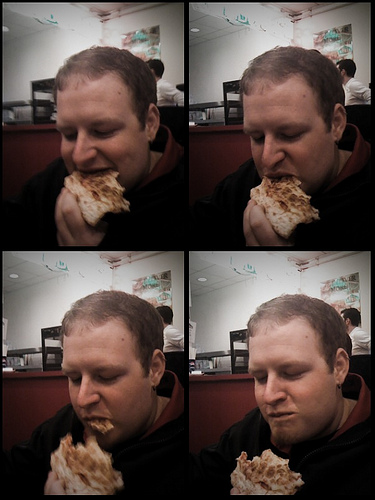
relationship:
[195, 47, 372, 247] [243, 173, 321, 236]
man eating pizza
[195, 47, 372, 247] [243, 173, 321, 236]
man biting pizza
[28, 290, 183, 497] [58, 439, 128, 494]
man chewing pizza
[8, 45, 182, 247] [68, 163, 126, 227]
man eating food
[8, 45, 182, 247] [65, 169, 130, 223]
man eating food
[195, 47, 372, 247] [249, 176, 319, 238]
man eating food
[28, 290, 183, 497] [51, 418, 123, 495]
man eating food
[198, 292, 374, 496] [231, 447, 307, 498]
man eating food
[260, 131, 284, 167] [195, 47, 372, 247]
nose of a man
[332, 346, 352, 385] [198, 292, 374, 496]
ear of a man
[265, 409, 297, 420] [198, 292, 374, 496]
lips of a man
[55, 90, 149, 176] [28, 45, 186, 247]
face of a man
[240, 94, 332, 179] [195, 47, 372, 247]
face of a man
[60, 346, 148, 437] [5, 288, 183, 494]
face of a man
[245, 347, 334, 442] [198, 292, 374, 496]
face of a man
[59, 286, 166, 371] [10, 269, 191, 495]
hair of a man